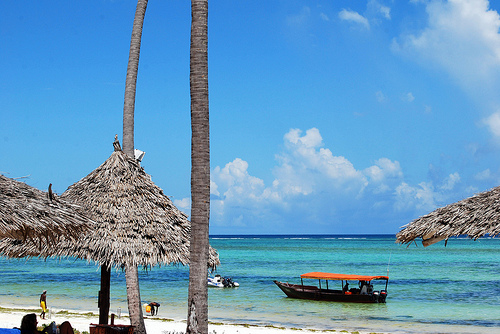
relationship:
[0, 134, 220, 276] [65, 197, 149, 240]
roof made of leaves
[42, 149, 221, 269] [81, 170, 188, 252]
roof made of leaves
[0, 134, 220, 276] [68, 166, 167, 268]
roof made of leaves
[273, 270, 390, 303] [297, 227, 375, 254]
boat in ocean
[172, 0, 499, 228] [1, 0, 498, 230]
clouds in blue sky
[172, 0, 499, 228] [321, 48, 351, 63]
clouds in sky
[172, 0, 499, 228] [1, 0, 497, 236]
clouds in blue sky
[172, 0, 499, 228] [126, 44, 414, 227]
clouds in sky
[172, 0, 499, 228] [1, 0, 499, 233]
clouds in sky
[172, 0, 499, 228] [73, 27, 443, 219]
clouds in sky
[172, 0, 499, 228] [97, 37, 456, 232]
clouds in sky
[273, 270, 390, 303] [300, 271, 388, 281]
boat with canopy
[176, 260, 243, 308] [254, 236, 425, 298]
boat in water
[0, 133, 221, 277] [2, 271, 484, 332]
umbrella on beach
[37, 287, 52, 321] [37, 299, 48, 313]
man in pants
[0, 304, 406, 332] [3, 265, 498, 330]
seaweed on shore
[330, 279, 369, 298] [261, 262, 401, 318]
people on boat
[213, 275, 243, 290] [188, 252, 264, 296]
engine on back of boat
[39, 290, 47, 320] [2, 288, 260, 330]
man on beach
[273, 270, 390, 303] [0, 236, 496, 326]
boat on water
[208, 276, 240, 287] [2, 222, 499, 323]
boat on water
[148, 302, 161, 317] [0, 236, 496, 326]
person in water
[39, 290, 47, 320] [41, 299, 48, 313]
man wearing swim trunks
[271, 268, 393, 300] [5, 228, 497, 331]
boat on water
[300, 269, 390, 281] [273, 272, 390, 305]
canopy on boat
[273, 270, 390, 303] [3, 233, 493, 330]
boat in ocean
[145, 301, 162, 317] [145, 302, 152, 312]
person carrying bucket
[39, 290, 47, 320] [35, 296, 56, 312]
man wearing shorts